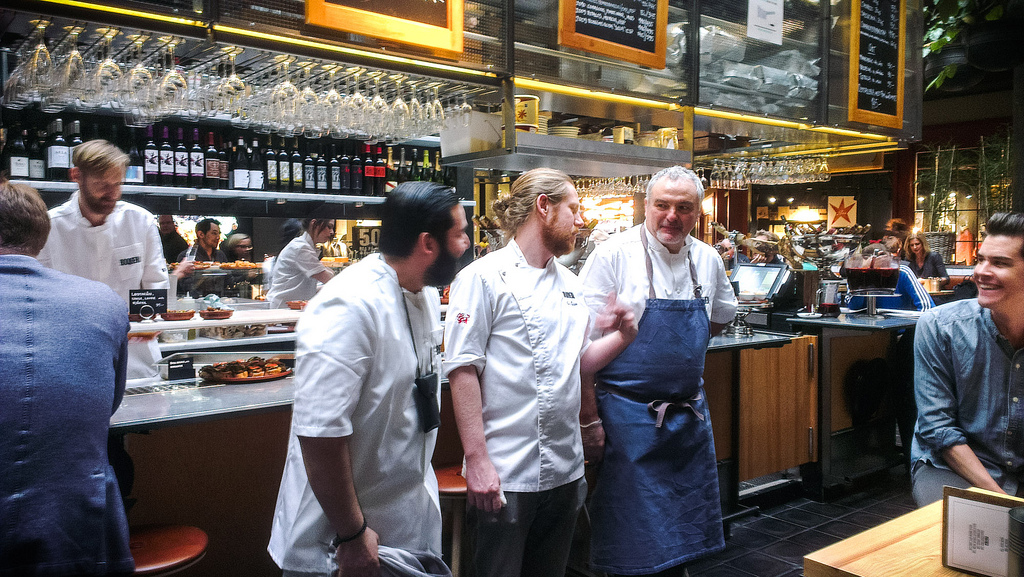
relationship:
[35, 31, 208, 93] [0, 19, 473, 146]
glasses in glasses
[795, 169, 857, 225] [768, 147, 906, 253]
star on wall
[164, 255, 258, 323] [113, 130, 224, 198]
vessel for drinking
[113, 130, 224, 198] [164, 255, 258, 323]
drinking for vessel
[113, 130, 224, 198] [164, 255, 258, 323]
drinking with vessel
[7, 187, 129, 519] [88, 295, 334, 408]
man at bar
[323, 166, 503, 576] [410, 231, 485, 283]
man has beard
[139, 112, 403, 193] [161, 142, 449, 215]
bottles on shelf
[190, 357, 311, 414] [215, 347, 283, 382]
tray of food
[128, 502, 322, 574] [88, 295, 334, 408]
stools at bar